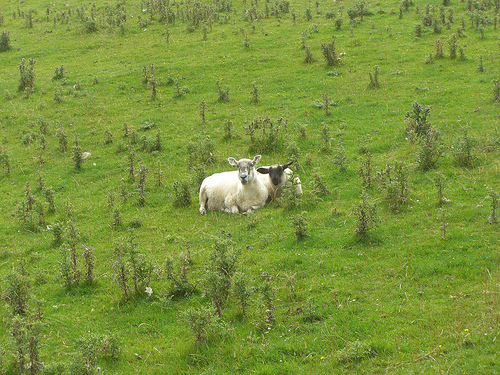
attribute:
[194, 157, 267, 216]
sheep — white, lying, looking, resting, sitting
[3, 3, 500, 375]
grass — long, green, yellow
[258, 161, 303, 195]
sheep — black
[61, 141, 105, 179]
flowers — yellow